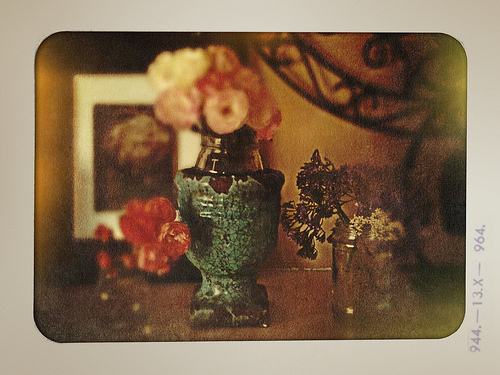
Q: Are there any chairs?
A: No, there are no chairs.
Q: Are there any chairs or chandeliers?
A: No, there are no chairs or chandeliers.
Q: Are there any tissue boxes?
A: No, there are no tissue boxes.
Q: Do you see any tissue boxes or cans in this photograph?
A: No, there are no tissue boxes or cans.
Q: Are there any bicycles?
A: No, there are no bicycles.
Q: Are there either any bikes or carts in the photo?
A: No, there are no bikes or carts.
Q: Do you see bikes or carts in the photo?
A: No, there are no bikes or carts.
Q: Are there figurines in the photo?
A: No, there are no figurines.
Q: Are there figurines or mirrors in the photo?
A: No, there are no figurines or mirrors.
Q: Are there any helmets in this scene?
A: No, there are no helmets.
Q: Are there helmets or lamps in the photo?
A: No, there are no helmets or lamps.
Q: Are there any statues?
A: No, there are no statues.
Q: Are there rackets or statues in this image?
A: No, there are no statues or rackets.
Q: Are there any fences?
A: No, there are no fences.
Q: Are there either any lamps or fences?
A: No, there are no fences or lamps.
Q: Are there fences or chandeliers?
A: No, there are no fences or chandeliers.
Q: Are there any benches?
A: No, there are no benches.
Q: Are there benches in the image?
A: No, there are no benches.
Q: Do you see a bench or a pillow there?
A: No, there are no benches or pillows.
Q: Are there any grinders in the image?
A: No, there are no grinders.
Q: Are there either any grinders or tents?
A: No, there are no grinders or tents.